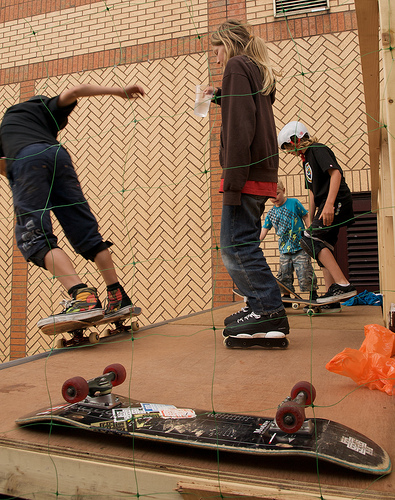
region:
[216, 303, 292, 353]
Girl wearing inline skates.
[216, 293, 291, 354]
Inline skates are black.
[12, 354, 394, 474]
Skateboard lying upside down.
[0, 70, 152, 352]
Boy riding on skateboard.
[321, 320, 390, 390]
Orange paper lying on ground.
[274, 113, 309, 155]
Boy wearing white helmet.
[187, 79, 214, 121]
Girl holding glass of water.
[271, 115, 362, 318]
Boy is flipping skateboard.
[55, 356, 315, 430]
Skateboard has red wheels.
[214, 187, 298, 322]
Girl is wearing blue jeans.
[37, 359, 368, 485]
upside down skateboard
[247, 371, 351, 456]
red skateboard wheels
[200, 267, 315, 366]
inline skates with white wheels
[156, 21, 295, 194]
blonde kid drinking water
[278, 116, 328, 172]
white safety helmet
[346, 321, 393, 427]
orange plastic on ground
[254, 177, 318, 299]
young boy learning to skate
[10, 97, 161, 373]
attempting a skateboard trick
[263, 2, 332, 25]
vent for heating/air system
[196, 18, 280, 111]
teen with blonde ponytail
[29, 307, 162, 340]
the skateboard at the edge of the ramp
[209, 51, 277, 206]
the jacket is brown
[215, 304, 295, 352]
the roller skate is black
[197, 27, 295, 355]
the person is wearing roller skate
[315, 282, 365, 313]
the sneakers is black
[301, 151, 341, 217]
the shirt is black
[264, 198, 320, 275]
the shirt is blue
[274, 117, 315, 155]
the helmet is white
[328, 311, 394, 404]
the plastic is orarnge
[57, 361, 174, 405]
the wheels are red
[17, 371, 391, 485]
a skate board with red wheels laying upside-down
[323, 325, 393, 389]
an orange plastic bag laying on the platform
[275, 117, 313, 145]
a white helmet the boy is wearing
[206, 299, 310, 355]
black roller skates the boy is wearing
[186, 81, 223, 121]
a clear plastic cup with water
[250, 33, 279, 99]
a blonde ponytail on the child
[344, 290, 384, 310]
a bunched up blue piece of clothing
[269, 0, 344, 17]
a white vent on the side of the building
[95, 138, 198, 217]
the brick on the building in a herringbone design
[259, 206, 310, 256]
a small boy's blue shirt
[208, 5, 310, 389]
female skateboarder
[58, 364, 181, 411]
red wheels on skateboard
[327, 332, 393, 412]
orange plastic trash bag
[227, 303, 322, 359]
black and white in line skates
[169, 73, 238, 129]
plastic cup with water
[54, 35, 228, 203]
brick wall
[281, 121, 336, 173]
white helmet on boy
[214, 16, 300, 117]
blond ponytail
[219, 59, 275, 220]
brown sweatshirt with red shirt underneath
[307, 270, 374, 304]
black and white checkered shoe